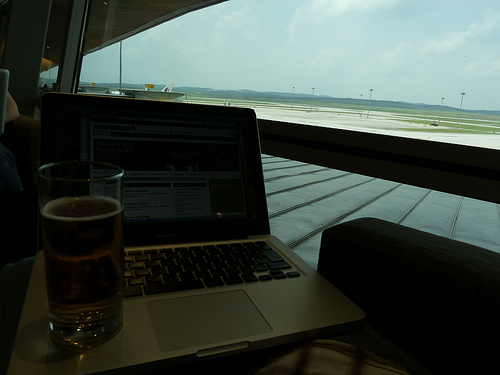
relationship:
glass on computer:
[36, 154, 128, 352] [5, 91, 368, 375]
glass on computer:
[35, 157, 125, 351] [14, 79, 376, 374]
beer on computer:
[39, 194, 125, 352] [5, 91, 368, 375]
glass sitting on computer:
[36, 154, 128, 352] [14, 79, 376, 374]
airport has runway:
[91, 66, 370, 245] [404, 108, 481, 145]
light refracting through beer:
[14, 321, 51, 360] [47, 259, 127, 289]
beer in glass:
[47, 259, 127, 289] [27, 150, 134, 349]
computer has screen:
[14, 79, 376, 374] [50, 105, 263, 238]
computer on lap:
[5, 91, 368, 375] [215, 330, 435, 362]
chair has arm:
[2, 212, 498, 374] [307, 214, 497, 372]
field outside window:
[187, 93, 498, 150] [77, 0, 498, 67]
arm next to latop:
[313, 215, 498, 356] [2, 90, 369, 373]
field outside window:
[259, 90, 498, 129] [71, 6, 498, 111]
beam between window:
[43, 4, 91, 92] [68, 0, 500, 154]